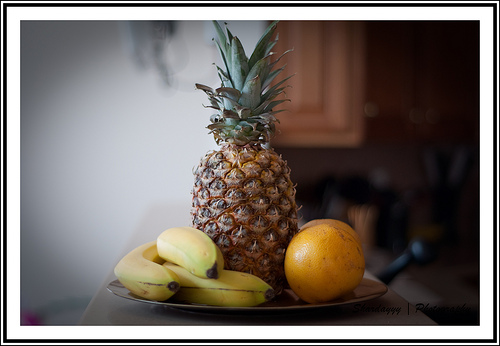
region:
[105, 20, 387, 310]
a plate full of fruit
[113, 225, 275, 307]
a bunch of three bananas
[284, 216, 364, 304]
a group of two oranges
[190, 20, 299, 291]
a pineapple on the plate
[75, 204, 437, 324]
a countertop in a kitchen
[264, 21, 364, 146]
part of a kitchen cabinet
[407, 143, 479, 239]
some kitchen utensils in the background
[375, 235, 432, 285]
a black kitchen utensil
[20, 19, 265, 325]
a white wall in the background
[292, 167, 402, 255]
a black kitchen appliance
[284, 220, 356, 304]
orange sitting on a plate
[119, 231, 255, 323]
bananas sitting on a plate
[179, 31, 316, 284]
uncut pineapple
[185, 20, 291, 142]
top of a pineapple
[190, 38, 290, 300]
pineapple sitting on a plate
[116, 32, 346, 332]
plate of fruit sitting on the counter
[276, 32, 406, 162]
open cabinet out of focus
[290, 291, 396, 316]
round plate sitting on the counter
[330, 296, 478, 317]
photography tag on picture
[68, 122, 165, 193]
wall behind the counter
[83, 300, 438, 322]
The counter is the color white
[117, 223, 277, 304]
The bananas on the plate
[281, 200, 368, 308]
The oranges on the plate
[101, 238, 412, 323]
The plate on the counter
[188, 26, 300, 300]
The pineapple on the plate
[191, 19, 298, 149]
The top of the pineapple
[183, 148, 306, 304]
The bottom of the pineapple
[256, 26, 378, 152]
A cabinet in the kitchen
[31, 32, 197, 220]
The wall at the end of the counter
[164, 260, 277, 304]
The end of the bananas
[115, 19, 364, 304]
the group of fruits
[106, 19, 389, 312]
the fruits on the plate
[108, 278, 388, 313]
the plate under the fruits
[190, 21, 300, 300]
the pineapple on the plate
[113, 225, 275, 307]
the bananas no the plate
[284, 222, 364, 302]
the orange on the plate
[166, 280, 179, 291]
the brown end of a banana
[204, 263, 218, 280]
the brown end of a banana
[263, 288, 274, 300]
the brown end of a banana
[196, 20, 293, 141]
the green stem on the pineapple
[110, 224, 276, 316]
Three bananas on a plate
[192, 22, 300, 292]
A brown and green pineapple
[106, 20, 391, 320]
A plate with fruit on it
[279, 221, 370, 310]
An orange on a plate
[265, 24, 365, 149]
A brown wooden cabinet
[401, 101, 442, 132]
Two handles on cabinets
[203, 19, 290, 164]
Green leaves on top of pineapple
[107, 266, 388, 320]
A round brown plate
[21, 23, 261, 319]
A wall that is white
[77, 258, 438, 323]
Plate is on a countertop